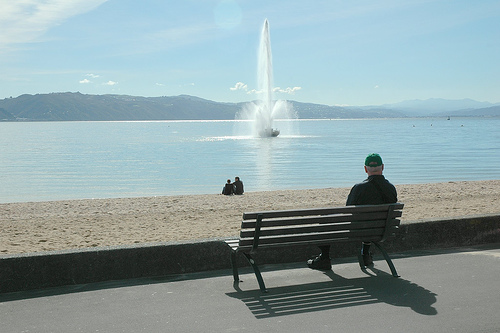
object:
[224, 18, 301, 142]
mist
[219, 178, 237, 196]
people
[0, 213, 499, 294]
curb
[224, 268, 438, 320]
shadow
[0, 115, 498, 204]
lake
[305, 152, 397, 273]
man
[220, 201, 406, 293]
bench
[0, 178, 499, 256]
sand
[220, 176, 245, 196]
couple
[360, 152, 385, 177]
head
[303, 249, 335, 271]
foot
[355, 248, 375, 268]
foot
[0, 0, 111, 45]
cloud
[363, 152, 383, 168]
hat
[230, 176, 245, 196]
people